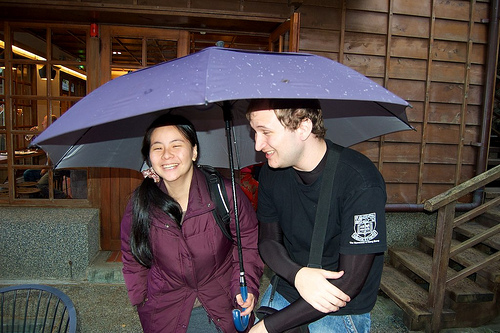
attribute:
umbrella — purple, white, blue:
[31, 47, 417, 172]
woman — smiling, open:
[120, 113, 267, 332]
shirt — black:
[260, 141, 389, 315]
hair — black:
[132, 113, 200, 267]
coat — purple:
[119, 172, 263, 333]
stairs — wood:
[380, 162, 499, 333]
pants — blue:
[255, 281, 371, 333]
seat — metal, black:
[0, 286, 81, 333]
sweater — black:
[258, 142, 388, 333]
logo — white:
[349, 212, 380, 246]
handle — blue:
[224, 105, 252, 332]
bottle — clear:
[23, 124, 35, 144]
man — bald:
[27, 114, 59, 138]